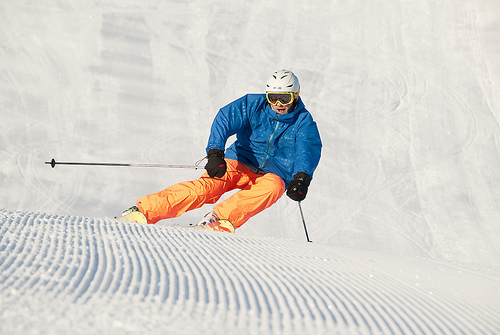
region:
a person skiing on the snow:
[60, 33, 387, 292]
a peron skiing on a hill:
[48, 23, 437, 275]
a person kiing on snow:
[57, 36, 343, 252]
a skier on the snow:
[54, 16, 411, 312]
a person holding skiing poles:
[37, 34, 361, 221]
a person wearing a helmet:
[248, 61, 328, 157]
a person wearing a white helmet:
[246, 61, 296, 111]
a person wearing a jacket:
[164, 61, 379, 222]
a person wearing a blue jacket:
[160, 63, 357, 211]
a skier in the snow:
[12, 46, 365, 258]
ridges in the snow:
[6, 212, 494, 332]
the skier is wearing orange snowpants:
[134, 147, 285, 232]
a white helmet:
[263, 67, 300, 93]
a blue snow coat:
[200, 88, 330, 176]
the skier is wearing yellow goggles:
[260, 87, 298, 105]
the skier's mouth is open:
[269, 99, 294, 115]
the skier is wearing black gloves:
[198, 147, 312, 200]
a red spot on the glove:
[215, 162, 229, 169]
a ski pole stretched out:
[42, 153, 214, 175]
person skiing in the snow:
[35, 62, 335, 245]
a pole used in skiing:
[43, 151, 210, 176]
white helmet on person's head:
[268, 64, 303, 91]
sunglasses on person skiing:
[265, 90, 295, 105]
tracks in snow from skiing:
[22, 234, 219, 296]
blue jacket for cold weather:
[207, 93, 325, 174]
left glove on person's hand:
[288, 170, 314, 203]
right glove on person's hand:
[200, 148, 227, 182]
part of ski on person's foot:
[186, 220, 235, 236]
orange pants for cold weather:
[139, 159, 285, 223]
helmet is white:
[257, 68, 309, 98]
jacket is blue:
[222, 99, 332, 171]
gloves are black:
[278, 176, 313, 200]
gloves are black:
[197, 150, 229, 182]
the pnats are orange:
[167, 171, 291, 221]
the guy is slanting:
[166, 89, 336, 257]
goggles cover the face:
[258, 86, 301, 116]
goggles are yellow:
[260, 89, 299, 109]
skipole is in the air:
[30, 146, 210, 181]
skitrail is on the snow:
[84, 212, 306, 309]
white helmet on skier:
[265, 66, 304, 94]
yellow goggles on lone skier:
[265, 91, 298, 106]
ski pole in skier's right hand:
[43, 158, 213, 172]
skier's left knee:
[252, 176, 287, 202]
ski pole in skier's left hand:
[293, 184, 315, 249]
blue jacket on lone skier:
[210, 91, 325, 183]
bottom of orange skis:
[118, 210, 244, 236]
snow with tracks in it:
[6, 208, 498, 333]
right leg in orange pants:
[135, 156, 250, 221]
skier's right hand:
[207, 153, 227, 177]